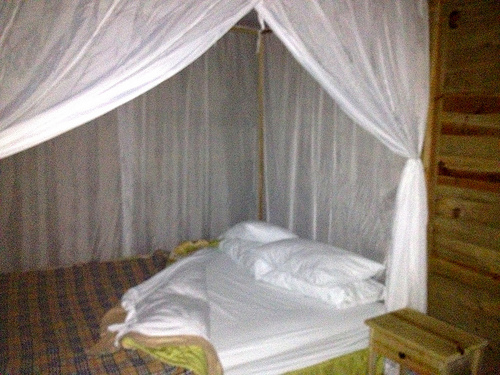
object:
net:
[1, 0, 427, 375]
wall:
[420, 0, 500, 375]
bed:
[0, 250, 387, 375]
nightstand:
[363, 306, 489, 374]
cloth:
[383, 155, 429, 375]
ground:
[433, 177, 464, 218]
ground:
[391, 156, 420, 190]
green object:
[122, 338, 208, 374]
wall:
[245, 141, 318, 196]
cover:
[0, 238, 389, 375]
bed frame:
[287, 347, 387, 375]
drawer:
[362, 306, 489, 374]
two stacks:
[217, 220, 298, 282]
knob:
[398, 351, 406, 359]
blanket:
[0, 248, 195, 374]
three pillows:
[216, 239, 385, 311]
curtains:
[0, 0, 430, 375]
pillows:
[216, 220, 389, 311]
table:
[362, 304, 490, 374]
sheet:
[107, 247, 387, 375]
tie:
[256, 15, 266, 55]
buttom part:
[384, 151, 444, 320]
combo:
[0, 214, 385, 375]